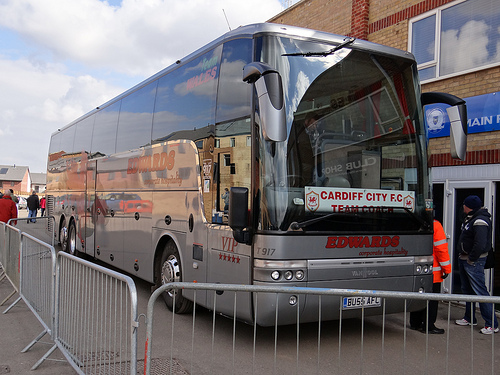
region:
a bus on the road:
[27, 41, 454, 373]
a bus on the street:
[19, 41, 455, 372]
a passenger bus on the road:
[4, 31, 499, 286]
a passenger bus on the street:
[8, 36, 498, 251]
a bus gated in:
[29, 61, 496, 351]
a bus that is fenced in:
[22, 23, 492, 314]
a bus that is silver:
[28, 38, 430, 357]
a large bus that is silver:
[42, 31, 486, 339]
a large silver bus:
[40, 7, 487, 355]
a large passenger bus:
[41, 25, 498, 347]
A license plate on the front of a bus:
[342, 290, 385, 310]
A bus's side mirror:
[226, 186, 253, 238]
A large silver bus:
[47, 39, 428, 327]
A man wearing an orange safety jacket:
[410, 220, 450, 334]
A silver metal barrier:
[4, 272, 498, 373]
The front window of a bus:
[263, 40, 425, 230]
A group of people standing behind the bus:
[2, 185, 49, 230]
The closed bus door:
[207, 126, 266, 325]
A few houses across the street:
[1, 164, 47, 204]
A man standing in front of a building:
[456, 196, 498, 335]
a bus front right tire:
[155, 238, 193, 314]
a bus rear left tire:
[66, 219, 76, 256]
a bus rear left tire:
[58, 218, 66, 250]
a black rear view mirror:
[225, 185, 246, 232]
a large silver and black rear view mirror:
[250, 73, 286, 143]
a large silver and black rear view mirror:
[445, 104, 467, 160]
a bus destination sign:
[302, 185, 416, 217]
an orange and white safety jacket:
[433, 220, 450, 282]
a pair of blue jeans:
[458, 262, 498, 327]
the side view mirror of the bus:
[243, 62, 288, 144]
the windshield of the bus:
[257, 40, 421, 230]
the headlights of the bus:
[270, 270, 306, 281]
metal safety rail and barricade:
[0, 282, 498, 374]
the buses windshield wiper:
[279, 35, 354, 57]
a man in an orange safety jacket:
[431, 219, 451, 281]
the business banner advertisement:
[303, 184, 415, 219]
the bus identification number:
[255, 244, 277, 257]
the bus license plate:
[344, 294, 381, 307]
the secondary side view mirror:
[227, 183, 252, 243]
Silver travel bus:
[42, 22, 437, 324]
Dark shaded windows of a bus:
[45, 35, 256, 230]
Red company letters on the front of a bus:
[322, 235, 409, 260]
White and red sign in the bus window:
[302, 184, 416, 217]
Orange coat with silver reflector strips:
[431, 216, 452, 283]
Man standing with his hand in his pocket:
[455, 194, 499, 334]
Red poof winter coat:
[0, 194, 18, 226]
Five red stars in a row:
[215, 250, 242, 264]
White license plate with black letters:
[341, 290, 384, 307]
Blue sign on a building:
[423, 89, 498, 141]